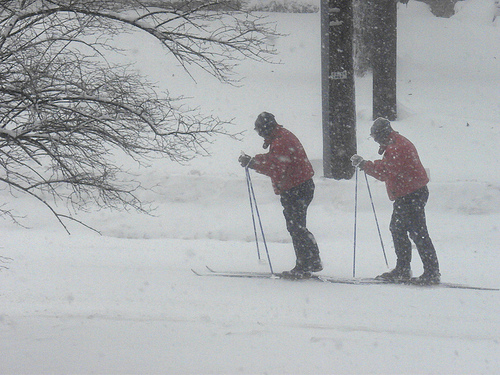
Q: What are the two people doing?
A: Skiing.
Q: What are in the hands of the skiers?
A: Ski poles.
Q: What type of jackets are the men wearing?
A: Red jackets.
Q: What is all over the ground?
A: Snow.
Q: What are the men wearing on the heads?
A: Hats.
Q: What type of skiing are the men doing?
A: Cross Country.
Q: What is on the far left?
A: A tree.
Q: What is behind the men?
A: A snowy hillside.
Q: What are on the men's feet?
A: Ski boots.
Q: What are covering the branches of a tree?
A: The snow.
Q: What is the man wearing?
A: A red jacket and black pants.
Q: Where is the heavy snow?
A: On the ground.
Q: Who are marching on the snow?
A: Skiers.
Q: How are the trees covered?
A: Bare.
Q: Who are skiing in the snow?
A: Two people.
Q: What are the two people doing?
A: Skiing.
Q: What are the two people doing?
A: Skiing.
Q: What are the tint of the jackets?
A: Red.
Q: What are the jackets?
A: The jackets are red.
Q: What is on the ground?
A: Snow on the ground.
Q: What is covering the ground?
A: Snow on the ground.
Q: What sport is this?
A: Cross country skiing.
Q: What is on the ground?
A: Snow.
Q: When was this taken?
A: Winter.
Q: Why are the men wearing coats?
A: Cold.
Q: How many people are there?
A: 2.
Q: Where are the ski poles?
A: People's hands.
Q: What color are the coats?
A: Red.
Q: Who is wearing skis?
A: People.